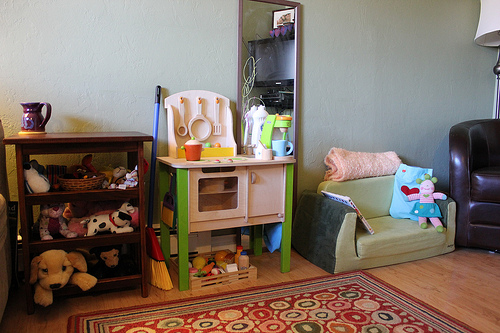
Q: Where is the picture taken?
A: A bedroom.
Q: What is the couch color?
A: Green.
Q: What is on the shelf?
A: Stuffed animals.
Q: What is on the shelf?
A: Toys.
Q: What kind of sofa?
A: Play.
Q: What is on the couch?
A: Toys.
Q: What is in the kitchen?
A: Oven.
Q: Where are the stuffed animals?
A: Bookcase.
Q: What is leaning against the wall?
A: A broom.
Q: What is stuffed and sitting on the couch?
A: A doll.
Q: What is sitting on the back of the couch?
A: A blanket.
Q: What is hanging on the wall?
A: A mirror.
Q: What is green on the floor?
A: A child's sofa.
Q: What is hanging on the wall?
A: A mirror.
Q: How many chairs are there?
A: Two.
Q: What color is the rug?
A: Red.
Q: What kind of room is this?
A: Living or play room.